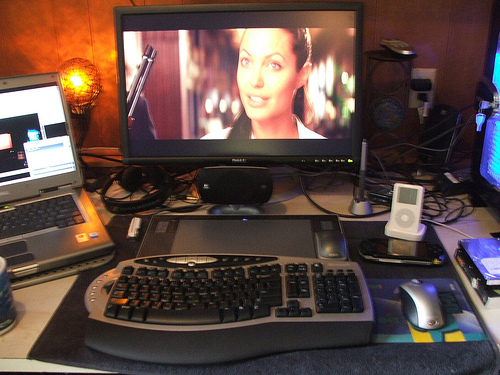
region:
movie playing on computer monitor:
[115, 6, 357, 165]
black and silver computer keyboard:
[85, 255, 370, 366]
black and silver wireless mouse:
[407, 275, 442, 330]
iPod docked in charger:
[386, 185, 426, 239]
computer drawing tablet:
[142, 214, 343, 258]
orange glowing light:
[59, 64, 99, 106]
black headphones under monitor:
[100, 166, 174, 213]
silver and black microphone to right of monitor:
[347, 141, 377, 216]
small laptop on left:
[2, 78, 114, 276]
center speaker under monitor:
[195, 170, 276, 206]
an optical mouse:
[341, 242, 478, 340]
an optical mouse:
[381, 258, 423, 347]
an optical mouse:
[394, 225, 449, 371]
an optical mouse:
[375, 300, 451, 346]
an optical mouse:
[385, 290, 462, 366]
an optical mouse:
[398, 211, 495, 361]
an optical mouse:
[360, 264, 454, 372]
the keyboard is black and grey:
[41, 155, 397, 345]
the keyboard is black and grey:
[94, 155, 269, 352]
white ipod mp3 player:
[392, 181, 421, 233]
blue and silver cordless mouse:
[398, 276, 444, 333]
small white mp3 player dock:
[381, 215, 426, 241]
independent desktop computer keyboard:
[86, 250, 373, 364]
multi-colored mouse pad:
[368, 270, 484, 345]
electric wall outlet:
[411, 64, 436, 113]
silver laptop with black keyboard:
[0, 66, 110, 284]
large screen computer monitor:
[112, 1, 357, 167]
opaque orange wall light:
[52, 55, 100, 115]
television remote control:
[376, 32, 418, 58]